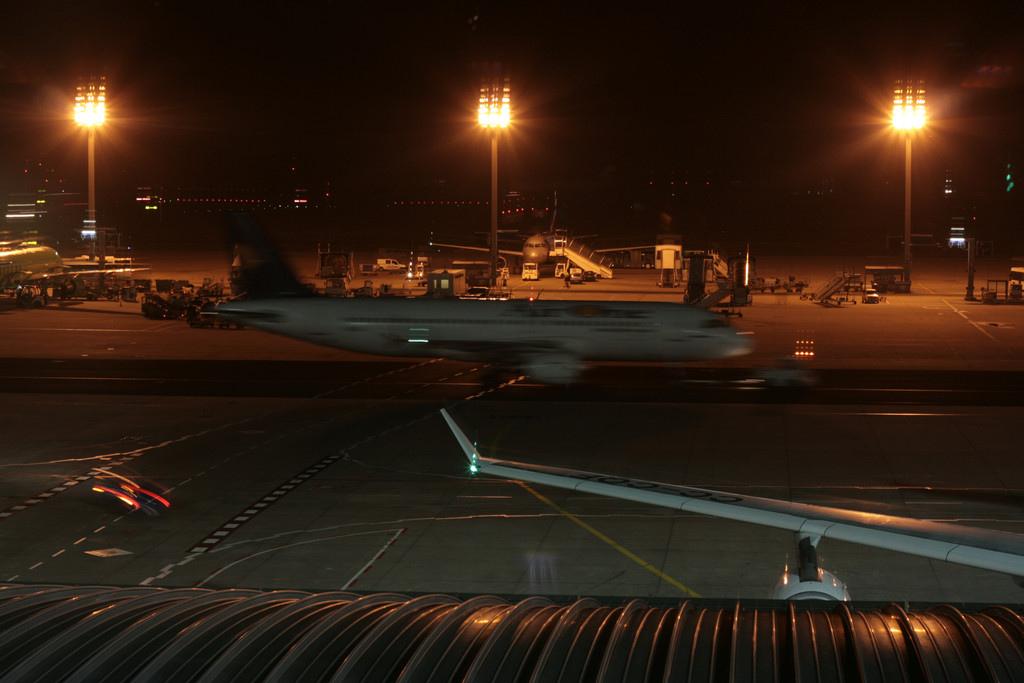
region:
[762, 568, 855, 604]
engine of a plane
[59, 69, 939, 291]
lights at the airport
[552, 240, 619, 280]
stairs leading up to plane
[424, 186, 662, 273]
plane sitting at the airport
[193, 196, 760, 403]
a plane either landing or taking off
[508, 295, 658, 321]
name of plane on the side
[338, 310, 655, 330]
windows on the plane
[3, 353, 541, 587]
lines marking off areas of airport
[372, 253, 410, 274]
white van parked on tarmac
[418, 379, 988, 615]
One wing on the side of the plane.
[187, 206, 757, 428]
Large white plane on the concrete.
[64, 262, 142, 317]
Loading truck on the runway.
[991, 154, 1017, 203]
Green light in the background.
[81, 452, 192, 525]
Orange and white stand on the road.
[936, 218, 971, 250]
White sign in the back of the road.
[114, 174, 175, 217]
Red and white sign past the light pole.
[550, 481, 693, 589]
Solid yellow stripe painted on the ground.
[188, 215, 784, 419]
white airplane on runway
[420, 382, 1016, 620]
white wing on plane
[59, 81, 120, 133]
lights on the runway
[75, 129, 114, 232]
pole connected to light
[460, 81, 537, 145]
light on the runway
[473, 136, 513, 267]
pole connected to light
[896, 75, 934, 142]
light on the runway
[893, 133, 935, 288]
pole connected to light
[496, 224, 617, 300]
plane landed on ground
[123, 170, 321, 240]
buildings behind the planes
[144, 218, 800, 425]
this is a plane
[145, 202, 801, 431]
the plane is white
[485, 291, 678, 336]
writing on the plane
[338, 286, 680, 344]
a row of windows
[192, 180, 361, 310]
tail of the plane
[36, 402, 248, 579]
dashes on the ground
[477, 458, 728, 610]
line on the ground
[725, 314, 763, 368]
nose on the plane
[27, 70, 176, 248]
The light to the left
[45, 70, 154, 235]
A light to the left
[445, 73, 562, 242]
The light in the middle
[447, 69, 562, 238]
A light in the middle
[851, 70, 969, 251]
A light to the right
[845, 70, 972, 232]
The light to the right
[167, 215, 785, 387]
A airplane on the tarmac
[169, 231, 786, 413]
The airplane on the tarmac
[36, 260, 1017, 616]
The black paved road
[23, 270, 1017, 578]
A black paved road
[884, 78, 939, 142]
Glare of the lights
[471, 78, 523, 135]
Glare of the lights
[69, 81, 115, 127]
Glare of the lights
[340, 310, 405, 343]
Windows on an airplane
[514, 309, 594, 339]
Windows on an airplane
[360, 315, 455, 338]
Windows on an airplane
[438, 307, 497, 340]
Windows on an airplane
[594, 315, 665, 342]
Windows on an airplane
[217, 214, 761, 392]
Blurry picture of a jet plane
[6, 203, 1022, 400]
Plane on the jetway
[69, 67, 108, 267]
A large airport spotlight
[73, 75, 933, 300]
Three spotlights at the airport at night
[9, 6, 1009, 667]
Planes landing and parked at night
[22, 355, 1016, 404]
An airport runway at night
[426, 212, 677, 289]
An airplane parked at night